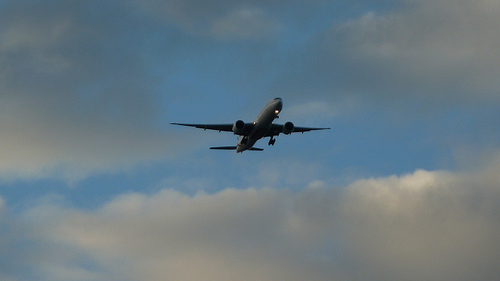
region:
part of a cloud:
[267, 172, 296, 212]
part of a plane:
[236, 123, 271, 172]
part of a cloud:
[383, 148, 423, 209]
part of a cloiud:
[388, 215, 411, 246]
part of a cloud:
[334, 209, 366, 248]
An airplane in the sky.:
[170, 84, 407, 199]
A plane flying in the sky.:
[157, 75, 362, 183]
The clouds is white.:
[46, 186, 433, 280]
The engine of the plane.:
[222, 108, 249, 150]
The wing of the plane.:
[178, 115, 230, 146]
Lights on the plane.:
[266, 99, 285, 125]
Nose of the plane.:
[263, 92, 283, 108]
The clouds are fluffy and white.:
[131, 164, 438, 257]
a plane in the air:
[153, 67, 355, 175]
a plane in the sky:
[147, 72, 353, 196]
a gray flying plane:
[144, 65, 354, 195]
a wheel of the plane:
[263, 132, 285, 157]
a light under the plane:
[269, 104, 281, 124]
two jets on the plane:
[223, 116, 313, 153]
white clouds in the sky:
[25, 21, 499, 277]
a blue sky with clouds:
[20, 8, 443, 277]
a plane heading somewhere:
[143, 60, 402, 193]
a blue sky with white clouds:
[21, 32, 496, 270]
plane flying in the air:
[182, 85, 324, 173]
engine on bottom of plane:
[222, 113, 257, 135]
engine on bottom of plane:
[281, 123, 291, 140]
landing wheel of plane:
[261, 109, 283, 120]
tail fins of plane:
[210, 142, 267, 153]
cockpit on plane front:
[270, 96, 287, 111]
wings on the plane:
[164, 119, 331, 139]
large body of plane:
[241, 98, 296, 149]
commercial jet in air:
[180, 95, 334, 173]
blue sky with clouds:
[1, 116, 199, 243]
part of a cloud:
[417, 196, 422, 207]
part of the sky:
[262, 173, 269, 179]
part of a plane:
[256, 122, 257, 136]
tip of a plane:
[275, 63, 284, 89]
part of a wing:
[246, 135, 248, 138]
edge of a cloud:
[271, 216, 293, 259]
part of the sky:
[181, 195, 190, 210]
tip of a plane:
[271, 95, 283, 120]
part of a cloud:
[269, 201, 277, 231]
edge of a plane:
[228, 127, 238, 157]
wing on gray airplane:
[167, 98, 330, 153]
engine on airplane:
[172, 93, 327, 155]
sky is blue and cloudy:
[1, 1, 498, 277]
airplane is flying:
[168, 98, 333, 155]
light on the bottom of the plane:
[164, 94, 333, 151]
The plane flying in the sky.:
[170, 69, 327, 170]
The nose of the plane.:
[269, 95, 281, 110]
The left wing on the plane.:
[275, 120, 336, 149]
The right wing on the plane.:
[176, 117, 254, 138]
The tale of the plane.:
[208, 147, 273, 159]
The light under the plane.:
[271, 107, 281, 114]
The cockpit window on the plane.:
[272, 96, 282, 103]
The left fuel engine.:
[280, 123, 297, 135]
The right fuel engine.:
[232, 117, 245, 135]